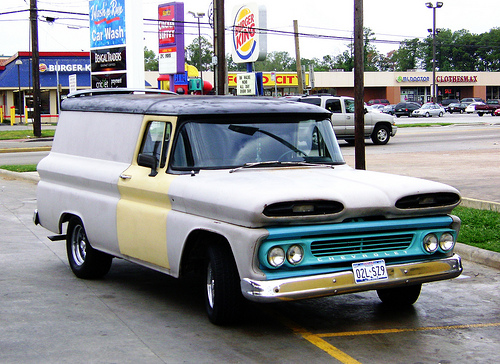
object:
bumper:
[240, 254, 463, 304]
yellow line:
[296, 323, 498, 364]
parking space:
[292, 315, 499, 363]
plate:
[351, 259, 389, 284]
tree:
[257, 50, 296, 72]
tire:
[203, 242, 239, 328]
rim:
[206, 264, 215, 308]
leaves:
[448, 204, 499, 254]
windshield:
[171, 121, 347, 168]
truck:
[31, 87, 462, 326]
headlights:
[266, 242, 305, 267]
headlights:
[421, 232, 455, 255]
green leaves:
[375, 26, 500, 70]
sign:
[230, 5, 269, 66]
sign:
[156, 1, 186, 77]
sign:
[88, 0, 143, 89]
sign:
[237, 71, 264, 95]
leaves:
[263, 50, 297, 73]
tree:
[417, 27, 483, 71]